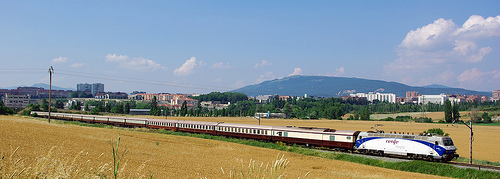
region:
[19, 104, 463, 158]
Long train on the tracks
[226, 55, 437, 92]
blue mountain in the background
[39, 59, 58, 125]
brown pole holding up wires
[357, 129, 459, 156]
blue and white part of train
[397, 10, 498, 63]
gray white clouds in sky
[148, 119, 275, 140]
windows on the train cars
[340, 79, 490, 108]
buildings in the background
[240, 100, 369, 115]
green trees in back of train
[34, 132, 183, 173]
brown field beside the train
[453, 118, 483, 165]
lamp post in front of the train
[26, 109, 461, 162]
Long trail of train carts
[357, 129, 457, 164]
Blue and white train pulling the rest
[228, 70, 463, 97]
Mountain in the background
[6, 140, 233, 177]
Brown grass next to the railroad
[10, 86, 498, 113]
Buildings in the background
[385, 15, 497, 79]
Clouds in the blue sky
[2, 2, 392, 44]
Blue sky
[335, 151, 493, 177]
Green shrubs by the train track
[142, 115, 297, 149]
Travel train compartments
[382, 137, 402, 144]
Train logo written in red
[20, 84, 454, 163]
the train is moving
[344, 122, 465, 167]
the front car is white, blue, and grey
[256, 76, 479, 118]
buildings to the right in the distance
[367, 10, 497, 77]
the clouds are white and fluffy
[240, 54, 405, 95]
a mountain in the background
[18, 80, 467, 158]
the train is very long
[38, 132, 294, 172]
the grass is yellowish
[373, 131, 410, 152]
red letters on the train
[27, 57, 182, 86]
wires in the air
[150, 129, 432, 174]
a line of green grass beside the train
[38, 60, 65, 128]
light post near train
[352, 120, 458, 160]
beginning of train, blue and white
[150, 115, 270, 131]
passengers in train traveling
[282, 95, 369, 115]
green trees in the distance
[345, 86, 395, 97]
factory building in a city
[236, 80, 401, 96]
beautiful mountains on the horizon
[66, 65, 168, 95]
electrical lines for power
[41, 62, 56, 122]
pole for stabilizing electric lines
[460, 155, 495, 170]
railroad tracks for the railroad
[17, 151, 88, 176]
flowing plants in the wind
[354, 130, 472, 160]
train car is blue and white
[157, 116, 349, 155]
train cars are beige and red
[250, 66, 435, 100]
mountain behind the buidlings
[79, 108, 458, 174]
farming fields are both sides of train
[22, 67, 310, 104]
power line above the train and fields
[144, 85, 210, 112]
red roofs on the buildings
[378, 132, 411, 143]
red writing on the train car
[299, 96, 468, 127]
trees along a field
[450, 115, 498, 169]
light along the track